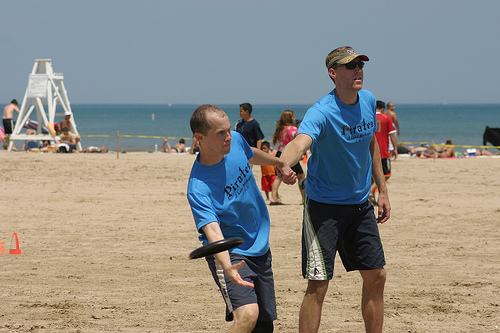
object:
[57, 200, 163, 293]
beach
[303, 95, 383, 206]
shirt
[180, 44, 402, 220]
two men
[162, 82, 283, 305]
man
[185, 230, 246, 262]
frisbee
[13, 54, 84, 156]
chair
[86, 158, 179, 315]
sand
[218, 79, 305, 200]
family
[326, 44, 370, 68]
cap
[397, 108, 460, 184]
people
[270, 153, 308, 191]
hands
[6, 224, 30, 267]
orange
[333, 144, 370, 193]
blue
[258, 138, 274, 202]
boy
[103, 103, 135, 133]
ocean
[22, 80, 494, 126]
background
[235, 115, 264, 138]
tee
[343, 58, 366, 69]
sunglasses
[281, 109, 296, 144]
woman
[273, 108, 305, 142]
pink shirt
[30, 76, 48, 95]
white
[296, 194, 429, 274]
shorts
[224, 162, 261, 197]
name of team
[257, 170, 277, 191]
shorts